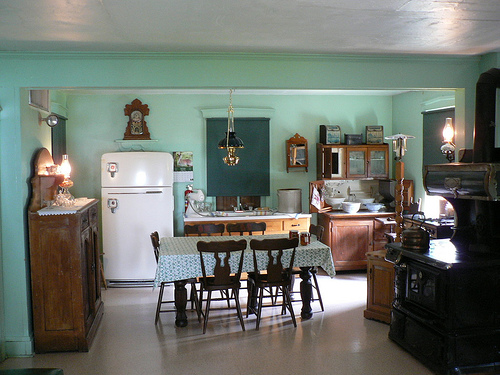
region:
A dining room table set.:
[152, 217, 332, 332]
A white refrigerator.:
[102, 152, 175, 290]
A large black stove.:
[385, 166, 497, 370]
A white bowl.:
[342, 200, 361, 212]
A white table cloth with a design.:
[154, 235, 337, 281]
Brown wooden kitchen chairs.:
[197, 240, 305, 336]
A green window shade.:
[204, 119, 273, 196]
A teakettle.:
[398, 209, 433, 251]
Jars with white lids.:
[291, 229, 312, 246]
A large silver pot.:
[276, 186, 303, 213]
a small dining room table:
[150, 220, 332, 340]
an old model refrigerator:
[103, 151, 176, 291]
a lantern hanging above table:
[214, 89, 244, 167]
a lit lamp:
[439, 113, 460, 163]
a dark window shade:
[204, 113, 269, 195]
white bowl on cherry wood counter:
[342, 198, 360, 212]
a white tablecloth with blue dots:
[155, 235, 339, 295]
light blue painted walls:
[2, 45, 497, 358]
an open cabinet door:
[315, 145, 342, 177]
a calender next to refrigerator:
[172, 151, 193, 183]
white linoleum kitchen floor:
[0, 273, 434, 373]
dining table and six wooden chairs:
[148, 221, 337, 336]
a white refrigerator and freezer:
[100, 151, 174, 287]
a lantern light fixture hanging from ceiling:
[217, 89, 246, 169]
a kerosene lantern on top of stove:
[440, 115, 456, 162]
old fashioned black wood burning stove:
[385, 70, 498, 372]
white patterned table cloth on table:
[153, 233, 336, 283]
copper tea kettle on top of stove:
[398, 212, 430, 250]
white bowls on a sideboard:
[323, 194, 385, 212]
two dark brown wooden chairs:
[193, 236, 299, 335]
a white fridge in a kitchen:
[99, 151, 174, 288]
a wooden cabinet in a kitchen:
[27, 147, 107, 354]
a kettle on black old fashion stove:
[398, 206, 430, 253]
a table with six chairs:
[148, 220, 336, 332]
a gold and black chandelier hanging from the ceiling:
[218, 90, 245, 167]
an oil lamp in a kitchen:
[440, 117, 460, 157]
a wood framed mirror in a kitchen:
[285, 133, 309, 173]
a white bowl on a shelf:
[341, 199, 362, 214]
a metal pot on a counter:
[277, 187, 302, 214]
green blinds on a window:
[206, 118, 271, 195]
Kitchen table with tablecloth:
[143, 221, 341, 337]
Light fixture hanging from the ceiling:
[212, 85, 249, 170]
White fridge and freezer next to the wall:
[95, 148, 179, 291]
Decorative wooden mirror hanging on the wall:
[281, 131, 310, 175]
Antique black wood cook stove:
[380, 64, 499, 373]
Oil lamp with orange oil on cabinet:
[50, 149, 75, 209]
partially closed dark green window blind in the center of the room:
[200, 111, 275, 201]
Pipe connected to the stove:
[468, 63, 498, 165]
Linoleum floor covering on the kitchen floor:
[30, 264, 424, 372]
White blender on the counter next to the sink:
[179, 181, 211, 221]